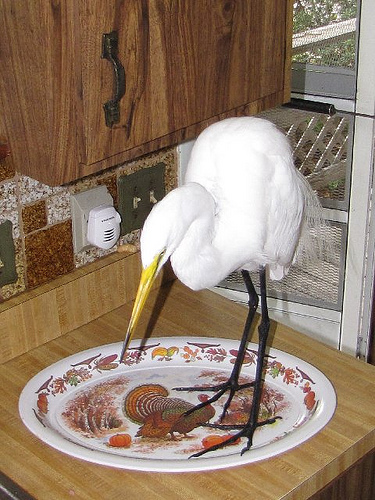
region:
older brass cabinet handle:
[99, 24, 129, 129]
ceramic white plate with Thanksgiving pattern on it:
[11, 327, 338, 475]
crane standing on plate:
[110, 116, 310, 464]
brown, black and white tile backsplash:
[0, 152, 187, 320]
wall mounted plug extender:
[68, 181, 126, 261]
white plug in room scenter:
[85, 201, 123, 251]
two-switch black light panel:
[115, 159, 170, 236]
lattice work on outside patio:
[238, 99, 354, 208]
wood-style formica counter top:
[4, 231, 372, 498]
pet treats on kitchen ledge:
[117, 235, 145, 252]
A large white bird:
[120, 115, 318, 470]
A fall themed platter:
[15, 336, 348, 478]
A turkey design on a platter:
[121, 383, 221, 443]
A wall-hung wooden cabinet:
[0, 0, 292, 188]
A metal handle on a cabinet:
[93, 25, 128, 137]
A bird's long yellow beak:
[118, 259, 168, 378]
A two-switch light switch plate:
[117, 171, 169, 230]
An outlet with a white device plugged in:
[70, 190, 124, 257]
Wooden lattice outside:
[270, 111, 350, 186]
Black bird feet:
[170, 366, 295, 461]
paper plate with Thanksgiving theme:
[16, 333, 339, 471]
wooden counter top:
[121, 282, 373, 464]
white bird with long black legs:
[111, 113, 325, 466]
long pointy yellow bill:
[115, 256, 160, 364]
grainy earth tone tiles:
[3, 183, 74, 295]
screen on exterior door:
[293, 23, 343, 323]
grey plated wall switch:
[111, 159, 169, 243]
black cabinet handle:
[90, 26, 130, 128]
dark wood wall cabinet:
[13, 4, 299, 182]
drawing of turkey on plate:
[122, 376, 217, 441]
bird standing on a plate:
[76, 122, 311, 460]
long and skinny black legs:
[174, 286, 296, 462]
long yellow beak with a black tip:
[99, 259, 159, 372]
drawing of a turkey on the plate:
[127, 370, 234, 450]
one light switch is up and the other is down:
[117, 175, 176, 224]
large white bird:
[84, 108, 342, 459]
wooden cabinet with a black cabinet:
[9, 5, 337, 188]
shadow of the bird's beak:
[131, 278, 177, 369]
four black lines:
[102, 227, 118, 242]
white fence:
[274, 103, 356, 195]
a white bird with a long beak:
[106, 117, 329, 370]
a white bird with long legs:
[130, 143, 318, 417]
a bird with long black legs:
[156, 183, 315, 458]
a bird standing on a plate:
[56, 133, 328, 483]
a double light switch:
[115, 158, 171, 223]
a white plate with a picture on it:
[9, 342, 325, 478]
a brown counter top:
[6, 305, 349, 498]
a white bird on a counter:
[87, 117, 322, 486]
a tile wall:
[3, 188, 66, 323]